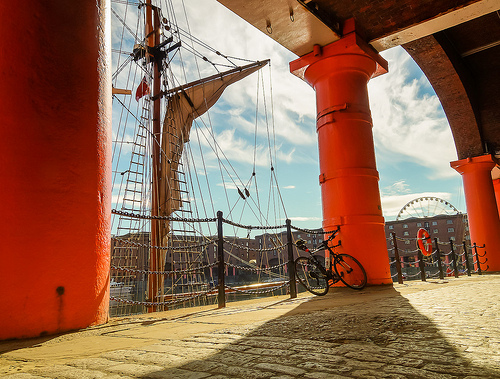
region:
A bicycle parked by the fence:
[289, 226, 366, 296]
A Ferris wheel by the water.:
[393, 197, 470, 277]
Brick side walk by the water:
[143, 293, 491, 343]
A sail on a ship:
[146, 57, 273, 299]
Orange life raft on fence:
[413, 226, 440, 261]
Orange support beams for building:
[3, 0, 112, 342]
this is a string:
[265, 62, 287, 164]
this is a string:
[250, 70, 267, 207]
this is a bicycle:
[290, 225, 372, 295]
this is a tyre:
[290, 255, 330, 305]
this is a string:
[390, 223, 489, 280]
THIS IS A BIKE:
[299, 228, 368, 293]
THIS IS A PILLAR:
[0, 0, 108, 325]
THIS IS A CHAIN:
[151, 213, 217, 225]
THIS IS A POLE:
[214, 205, 230, 308]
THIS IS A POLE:
[285, 222, 295, 304]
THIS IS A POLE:
[390, 231, 407, 284]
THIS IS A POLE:
[434, 240, 444, 280]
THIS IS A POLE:
[445, 234, 460, 280]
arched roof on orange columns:
[1, 2, 498, 339]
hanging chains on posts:
[110, 207, 486, 314]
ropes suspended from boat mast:
[110, 1, 300, 313]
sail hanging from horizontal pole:
[158, 61, 268, 305]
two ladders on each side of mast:
[110, 61, 210, 311]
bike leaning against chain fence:
[286, 221, 369, 294]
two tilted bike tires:
[295, 253, 368, 295]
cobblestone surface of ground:
[0, 273, 499, 376]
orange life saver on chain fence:
[387, 223, 486, 279]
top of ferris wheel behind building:
[395, 194, 460, 266]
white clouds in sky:
[380, 88, 432, 178]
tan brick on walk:
[336, 313, 449, 377]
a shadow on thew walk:
[231, 283, 456, 377]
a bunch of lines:
[100, 11, 290, 211]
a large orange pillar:
[315, 56, 395, 218]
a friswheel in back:
[389, 194, 462, 224]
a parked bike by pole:
[274, 218, 390, 300]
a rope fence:
[72, 205, 485, 345]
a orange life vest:
[416, 221, 437, 265]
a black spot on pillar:
[33, 270, 85, 337]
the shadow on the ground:
[280, 318, 361, 378]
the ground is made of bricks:
[264, 333, 333, 370]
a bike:
[286, 237, 375, 292]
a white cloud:
[276, 95, 310, 144]